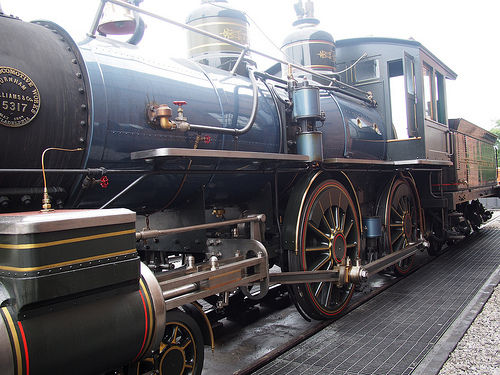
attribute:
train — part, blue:
[20, 65, 449, 258]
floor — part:
[238, 334, 291, 347]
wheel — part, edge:
[300, 183, 355, 309]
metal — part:
[147, 6, 200, 48]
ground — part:
[405, 317, 471, 346]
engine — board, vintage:
[208, 47, 259, 71]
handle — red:
[85, 174, 113, 198]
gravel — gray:
[305, 337, 343, 361]